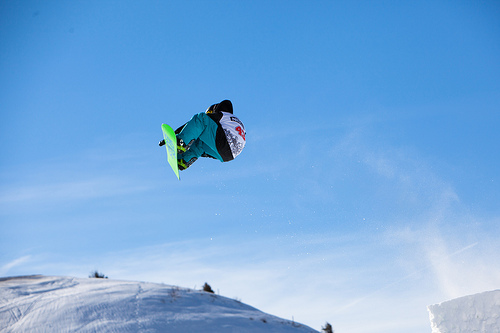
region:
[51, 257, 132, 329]
white snow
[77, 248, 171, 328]
white snow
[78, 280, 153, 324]
white snow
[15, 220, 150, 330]
white snow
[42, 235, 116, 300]
white snow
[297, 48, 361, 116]
blue sky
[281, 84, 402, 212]
blue sky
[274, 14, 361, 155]
blue sky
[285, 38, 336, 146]
blue sky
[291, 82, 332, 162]
blue sky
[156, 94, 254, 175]
snowboarder performing tricks on mountain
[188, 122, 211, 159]
snowboarder wearing green pants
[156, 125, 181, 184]
green snowboard used by man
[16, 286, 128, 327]
white snow on top of mountain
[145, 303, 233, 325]
white snow on top of mountain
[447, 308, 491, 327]
white snow on top of mountain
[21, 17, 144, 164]
white clouds against blue sky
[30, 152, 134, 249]
white clouds against blue sky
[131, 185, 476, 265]
white clouds against blue sky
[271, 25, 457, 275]
white clouds against blue sky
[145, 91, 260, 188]
person riding a snowboard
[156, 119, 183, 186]
snowboard with green bottom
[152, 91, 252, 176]
person wearing blue pants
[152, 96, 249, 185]
person wearing white jacket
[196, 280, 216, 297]
tip of an evergreen tree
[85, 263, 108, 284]
v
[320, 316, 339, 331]
tip of an evergreen tree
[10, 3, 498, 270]
the sky is clear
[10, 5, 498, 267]
the sky has wispy clouds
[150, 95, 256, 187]
person in the air on a snowboard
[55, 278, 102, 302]
white snow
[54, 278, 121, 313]
white snow